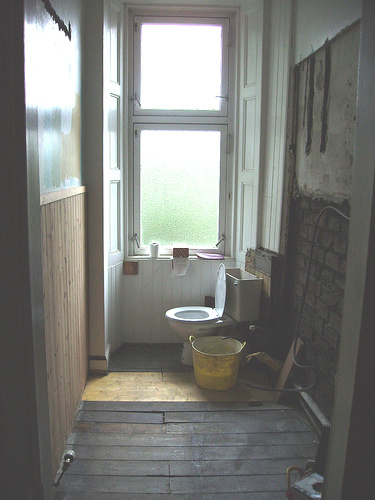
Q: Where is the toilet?
A: Next to the window.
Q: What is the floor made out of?
A: Wood planks.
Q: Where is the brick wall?
A: To left of toilet.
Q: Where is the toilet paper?
A: Under window.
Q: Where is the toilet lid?
A: Up.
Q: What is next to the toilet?
A: Yellow bin.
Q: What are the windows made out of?
A: Frosted glass.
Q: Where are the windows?
A: On the far wall.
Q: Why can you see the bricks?
A: Wall is exposed.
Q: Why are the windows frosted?
A: Privacy.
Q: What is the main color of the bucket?
A: Yellow.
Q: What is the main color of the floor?
A: Brown.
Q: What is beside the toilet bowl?
A: A pail.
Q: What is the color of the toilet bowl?
A: White.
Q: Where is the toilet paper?
A: By the window.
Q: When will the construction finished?
A: Next week.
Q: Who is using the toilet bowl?
A: No one.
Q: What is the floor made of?
A: Wood.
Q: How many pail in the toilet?
A: One.